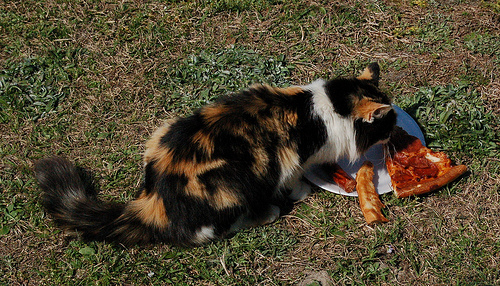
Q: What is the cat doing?
A: Eating pizza.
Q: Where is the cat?
A: On grass.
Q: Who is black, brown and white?
A: The cat.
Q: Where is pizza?
A: On a plate.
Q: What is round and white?
A: The plate.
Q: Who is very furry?
A: A cat.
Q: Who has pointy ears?
A: Cat.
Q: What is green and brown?
A: The grass.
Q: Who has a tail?
A: A cat.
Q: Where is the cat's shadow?
A: On the plate.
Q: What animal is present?
A: Cat.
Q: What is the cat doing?
A: Eating.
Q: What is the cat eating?
A: Pizza.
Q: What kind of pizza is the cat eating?
A: Pepperoni.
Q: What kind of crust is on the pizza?
A: Hand-tossed.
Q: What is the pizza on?
A: Plate.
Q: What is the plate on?
A: Grass.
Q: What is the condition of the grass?
A: Dry.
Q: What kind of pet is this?
A: Cat.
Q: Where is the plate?
A: Under the pizza.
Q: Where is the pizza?
A: On plate.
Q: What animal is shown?
A: Cat.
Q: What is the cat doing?
A: Eating.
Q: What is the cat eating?
A: Pizza.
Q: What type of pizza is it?
A: Pepperoni.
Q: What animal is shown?
A: A cat.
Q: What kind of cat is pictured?
A: A calico.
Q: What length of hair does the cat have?
A: Long hair.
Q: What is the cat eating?
A: Pizza.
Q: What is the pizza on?
A: A white plate.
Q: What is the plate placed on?
A: Grass.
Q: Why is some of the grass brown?
A: It is dead.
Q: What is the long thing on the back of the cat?
A: Its tail.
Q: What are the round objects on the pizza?
A: Pepperonis.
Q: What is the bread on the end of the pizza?
A: The crust.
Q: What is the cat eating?
A: Pizza.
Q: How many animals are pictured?
A: 1.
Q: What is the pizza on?
A: Plate.